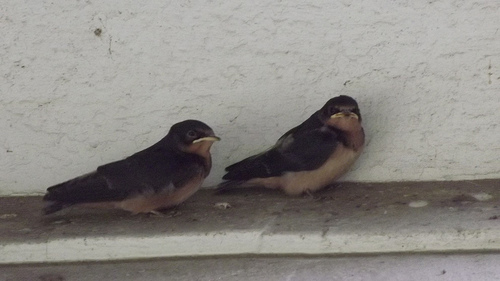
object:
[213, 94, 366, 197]
bird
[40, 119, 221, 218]
bird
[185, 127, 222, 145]
beak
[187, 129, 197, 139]
eye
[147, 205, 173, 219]
foot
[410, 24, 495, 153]
wall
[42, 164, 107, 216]
tail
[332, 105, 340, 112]
black eye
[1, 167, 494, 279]
ledge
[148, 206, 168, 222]
legs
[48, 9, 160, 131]
wall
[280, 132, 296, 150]
feathers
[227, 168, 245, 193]
feathers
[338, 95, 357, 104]
feathers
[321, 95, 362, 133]
head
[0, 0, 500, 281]
buillding